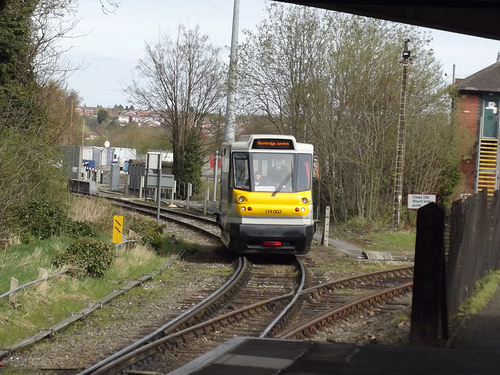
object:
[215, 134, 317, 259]
train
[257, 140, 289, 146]
lettering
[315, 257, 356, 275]
grass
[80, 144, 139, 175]
building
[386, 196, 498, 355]
fence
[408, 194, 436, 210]
sign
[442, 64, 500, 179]
building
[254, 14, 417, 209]
trees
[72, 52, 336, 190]
background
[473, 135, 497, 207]
stairs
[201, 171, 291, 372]
track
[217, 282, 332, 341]
line junction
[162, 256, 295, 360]
junction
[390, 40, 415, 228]
ladder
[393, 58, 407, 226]
utility pole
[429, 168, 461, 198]
bush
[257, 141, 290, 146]
sign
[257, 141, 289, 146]
destination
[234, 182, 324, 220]
front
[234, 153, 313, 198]
windshield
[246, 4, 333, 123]
branches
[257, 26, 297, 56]
no leaves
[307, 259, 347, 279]
gravel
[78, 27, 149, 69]
sky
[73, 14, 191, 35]
cloud cover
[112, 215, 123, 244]
sign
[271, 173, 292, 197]
windshield wiper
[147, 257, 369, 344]
ground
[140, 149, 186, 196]
buildings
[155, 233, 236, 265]
shadow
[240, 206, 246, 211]
lights